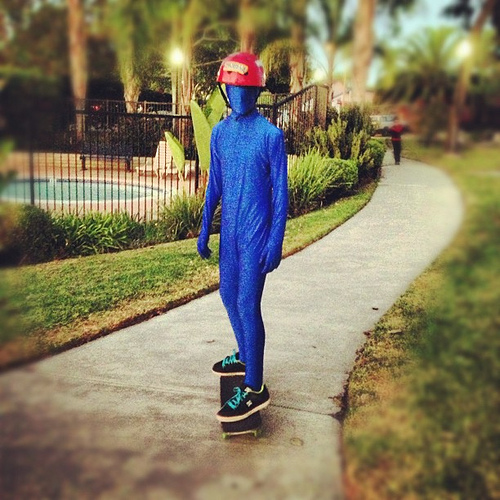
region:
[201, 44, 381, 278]
a man wearing helmet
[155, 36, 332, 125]
a man wearing a red helmet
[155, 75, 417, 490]
a man wearing blue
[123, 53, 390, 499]
a man riding a skateboaord on a sidewalk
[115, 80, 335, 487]
a man on the sidewalk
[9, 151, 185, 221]
a pool behind a fence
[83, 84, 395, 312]
a black metal fence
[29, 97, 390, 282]
a tall metal fence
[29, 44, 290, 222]
a tall black metal fence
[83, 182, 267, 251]
bushes along the fence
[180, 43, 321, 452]
person standing on a skateboard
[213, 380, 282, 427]
blue shoelaces on the shoe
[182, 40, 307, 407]
person wearing a blue bodysuit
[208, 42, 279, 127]
red helmet on the head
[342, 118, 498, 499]
grass on the ground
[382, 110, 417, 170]
person walking on the sidewalk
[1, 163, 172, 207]
an in ground pool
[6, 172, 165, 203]
light blue water in the pool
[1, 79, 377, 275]
plants along the fence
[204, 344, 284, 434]
both feet on the skateboard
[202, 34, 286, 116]
The helmet is red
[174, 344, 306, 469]
The person is on a board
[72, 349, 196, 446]
The concrete is gray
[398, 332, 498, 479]
The grass is patchy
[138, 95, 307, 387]
The person has a blue suit on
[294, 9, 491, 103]
It is day time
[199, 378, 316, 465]
The person has sneakers on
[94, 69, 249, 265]
The fence is metal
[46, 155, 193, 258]
The pool is in the back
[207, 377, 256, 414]
The shoe laces are blue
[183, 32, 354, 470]
a man wearing all blue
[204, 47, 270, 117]
the head of a man in blue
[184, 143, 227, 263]
the arm of a man in blue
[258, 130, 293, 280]
the arm of a man in blue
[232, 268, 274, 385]
the leg of a man in blue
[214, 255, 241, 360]
the leg of a man in blue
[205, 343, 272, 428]
the shoes of a man in blue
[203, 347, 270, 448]
the skateboard of a man in blue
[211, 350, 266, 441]
a black skateboard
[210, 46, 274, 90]
a red skateboarding helmet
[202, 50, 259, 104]
person wearing red helmet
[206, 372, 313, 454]
shoes with green strings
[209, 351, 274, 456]
person on black skateboard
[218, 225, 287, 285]
person in blue coverall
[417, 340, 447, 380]
green foliage by sidewalk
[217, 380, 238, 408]
shoes are black and white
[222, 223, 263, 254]
zipper on blue coverall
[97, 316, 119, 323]
brown and green grass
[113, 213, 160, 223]
metal gate behind sidewalk